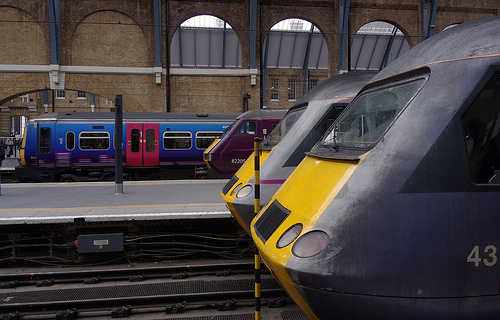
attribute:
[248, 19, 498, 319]
engine — yellow, grey, black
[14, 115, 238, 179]
car — blue, black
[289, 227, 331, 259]
light — round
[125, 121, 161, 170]
door — red, pink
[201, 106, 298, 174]
train — purple, parked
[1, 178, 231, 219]
platform — gray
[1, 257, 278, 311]
track — brown, metal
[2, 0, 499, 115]
wall — brown, tan, brick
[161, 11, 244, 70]
window — arched, archd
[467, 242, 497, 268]
number — white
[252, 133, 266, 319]
pole — yellow